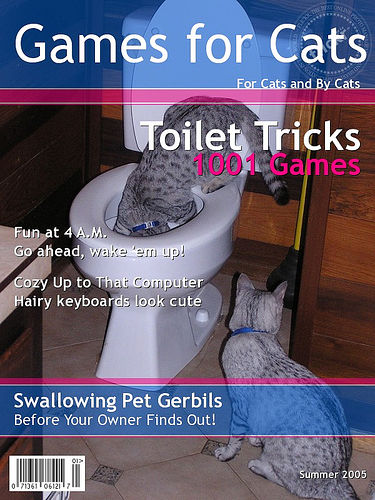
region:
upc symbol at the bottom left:
[5, 446, 96, 495]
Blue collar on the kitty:
[105, 201, 205, 235]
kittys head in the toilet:
[90, 188, 220, 242]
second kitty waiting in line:
[213, 270, 357, 498]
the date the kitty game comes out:
[298, 463, 371, 486]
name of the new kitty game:
[132, 114, 367, 187]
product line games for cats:
[9, 13, 365, 75]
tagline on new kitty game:
[12, 220, 196, 262]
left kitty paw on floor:
[208, 441, 243, 466]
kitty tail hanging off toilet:
[235, 97, 292, 206]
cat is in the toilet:
[106, 219, 174, 249]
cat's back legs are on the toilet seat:
[212, 144, 221, 206]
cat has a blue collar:
[125, 216, 163, 226]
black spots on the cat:
[151, 164, 197, 202]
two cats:
[110, 204, 268, 349]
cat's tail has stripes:
[264, 154, 288, 199]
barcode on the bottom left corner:
[20, 460, 66, 483]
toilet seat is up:
[124, 102, 153, 125]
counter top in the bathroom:
[17, 244, 43, 298]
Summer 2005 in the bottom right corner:
[302, 463, 367, 483]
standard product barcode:
[9, 454, 87, 491]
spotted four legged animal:
[205, 272, 365, 496]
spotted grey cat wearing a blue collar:
[211, 261, 362, 497]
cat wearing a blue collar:
[221, 263, 355, 498]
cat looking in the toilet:
[67, 10, 300, 340]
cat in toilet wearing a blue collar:
[89, 96, 289, 307]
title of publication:
[6, 13, 369, 100]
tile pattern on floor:
[90, 438, 194, 498]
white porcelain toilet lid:
[131, 7, 288, 186]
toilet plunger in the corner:
[257, 80, 306, 313]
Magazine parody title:
[12, 17, 369, 89]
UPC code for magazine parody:
[4, 452, 88, 495]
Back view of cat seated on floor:
[221, 268, 361, 497]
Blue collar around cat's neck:
[220, 324, 285, 340]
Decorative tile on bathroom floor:
[86, 461, 125, 487]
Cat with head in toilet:
[111, 93, 290, 238]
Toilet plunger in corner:
[263, 78, 318, 308]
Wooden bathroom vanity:
[2, 286, 48, 497]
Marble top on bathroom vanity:
[0, 217, 54, 325]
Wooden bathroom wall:
[0, 5, 108, 282]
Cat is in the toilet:
[110, 91, 290, 239]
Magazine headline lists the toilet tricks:
[141, 119, 373, 183]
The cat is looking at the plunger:
[214, 263, 357, 498]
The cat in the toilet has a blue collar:
[111, 196, 183, 251]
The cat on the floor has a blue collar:
[213, 282, 292, 349]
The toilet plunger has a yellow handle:
[278, 46, 329, 312]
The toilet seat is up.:
[121, 3, 269, 166]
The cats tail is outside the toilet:
[225, 100, 298, 209]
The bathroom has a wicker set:
[3, 204, 97, 498]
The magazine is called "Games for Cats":
[7, 17, 370, 72]